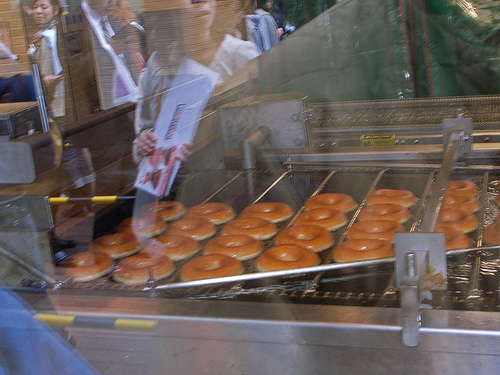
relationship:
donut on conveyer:
[178, 254, 243, 284] [7, 154, 498, 320]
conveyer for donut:
[7, 154, 498, 320] [178, 254, 243, 284]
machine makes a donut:
[4, 96, 499, 375] [178, 254, 243, 284]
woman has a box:
[132, 0, 280, 182] [138, 56, 220, 201]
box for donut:
[138, 56, 220, 201] [178, 254, 243, 284]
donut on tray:
[178, 254, 243, 284] [50, 192, 499, 282]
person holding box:
[132, 0, 280, 182] [138, 56, 220, 201]